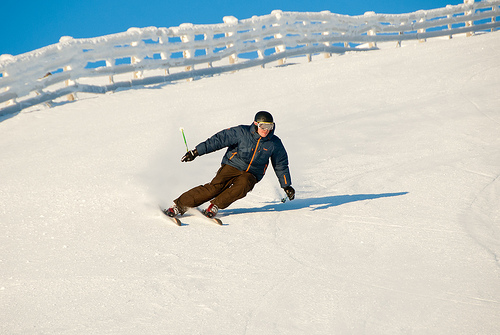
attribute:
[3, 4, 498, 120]
fence — long, wooden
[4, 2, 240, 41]
sky — blue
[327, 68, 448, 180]
snow — white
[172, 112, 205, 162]
ski stick — green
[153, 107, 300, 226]
man — skiing, standing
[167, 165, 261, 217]
pants — brown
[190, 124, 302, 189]
coat — blue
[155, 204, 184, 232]
ski — blue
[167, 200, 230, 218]
boots — red